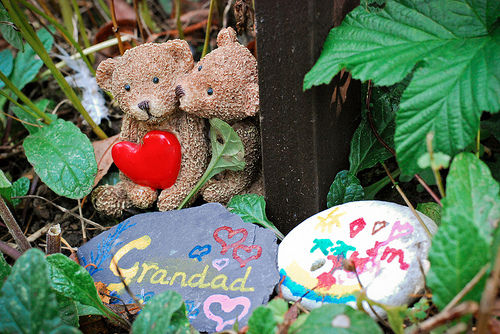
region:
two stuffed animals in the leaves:
[89, 49, 271, 181]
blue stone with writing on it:
[97, 218, 274, 321]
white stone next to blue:
[273, 203, 424, 312]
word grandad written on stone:
[100, 240, 257, 290]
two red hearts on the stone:
[217, 220, 250, 278]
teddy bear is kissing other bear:
[76, 34, 269, 122]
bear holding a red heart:
[96, 81, 187, 201]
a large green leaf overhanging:
[342, 15, 497, 164]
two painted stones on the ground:
[65, 199, 437, 333]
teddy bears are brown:
[111, 39, 251, 131]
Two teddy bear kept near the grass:
[93, 45, 258, 199]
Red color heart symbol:
[101, 132, 196, 188]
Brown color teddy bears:
[86, 39, 261, 218]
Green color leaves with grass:
[2, 0, 499, 333]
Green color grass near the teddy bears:
[23, 4, 97, 92]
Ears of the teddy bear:
[218, 28, 270, 111]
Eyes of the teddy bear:
[194, 64, 218, 101]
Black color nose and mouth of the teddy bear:
[131, 99, 165, 129]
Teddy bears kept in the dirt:
[38, 27, 278, 226]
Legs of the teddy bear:
[93, 183, 231, 210]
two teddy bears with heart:
[63, 32, 263, 203]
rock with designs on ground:
[278, 193, 438, 318]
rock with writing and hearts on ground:
[72, 202, 286, 332]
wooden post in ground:
[252, 7, 377, 209]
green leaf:
[29, 112, 102, 209]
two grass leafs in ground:
[50, 35, 90, 109]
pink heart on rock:
[194, 289, 259, 331]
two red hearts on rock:
[213, 218, 269, 265]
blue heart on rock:
[185, 239, 213, 269]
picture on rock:
[308, 220, 409, 296]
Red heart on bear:
[108, 126, 189, 191]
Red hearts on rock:
[211, 218, 265, 270]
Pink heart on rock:
[197, 288, 252, 331]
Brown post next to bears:
[260, 0, 320, 236]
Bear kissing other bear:
[176, 22, 266, 212]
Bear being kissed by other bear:
[85, 34, 208, 219]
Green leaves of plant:
[297, 0, 499, 195]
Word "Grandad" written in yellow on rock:
[98, 234, 259, 296]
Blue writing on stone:
[307, 235, 358, 263]